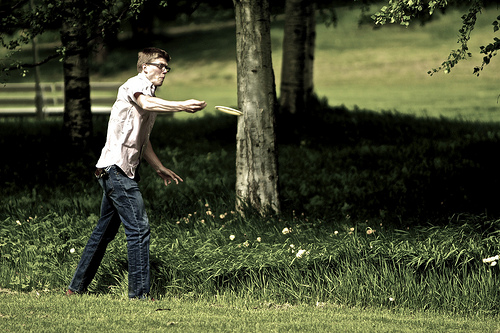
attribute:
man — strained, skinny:
[82, 34, 187, 312]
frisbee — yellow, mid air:
[206, 98, 250, 129]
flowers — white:
[207, 208, 323, 262]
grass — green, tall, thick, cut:
[389, 264, 440, 303]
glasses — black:
[140, 59, 181, 80]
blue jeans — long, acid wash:
[77, 161, 164, 288]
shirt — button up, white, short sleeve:
[114, 66, 167, 192]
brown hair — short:
[129, 50, 186, 54]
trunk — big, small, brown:
[230, 4, 290, 93]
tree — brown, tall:
[57, 63, 95, 193]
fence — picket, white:
[6, 74, 42, 116]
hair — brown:
[142, 49, 173, 62]